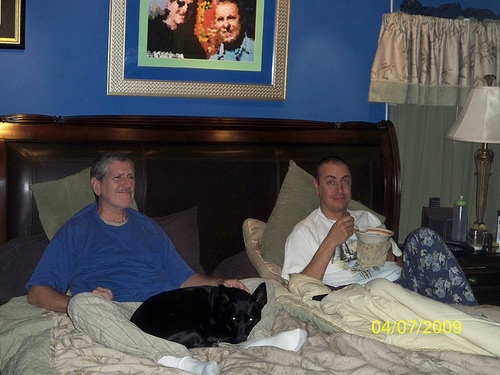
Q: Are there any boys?
A: No, there are no boys.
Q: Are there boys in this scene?
A: No, there are no boys.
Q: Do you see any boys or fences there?
A: No, there are no boys or fences.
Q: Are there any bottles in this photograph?
A: Yes, there is a bottle.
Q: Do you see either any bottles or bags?
A: Yes, there is a bottle.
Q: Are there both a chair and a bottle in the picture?
A: No, there is a bottle but no chairs.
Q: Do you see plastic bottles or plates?
A: Yes, there is a plastic bottle.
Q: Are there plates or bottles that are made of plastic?
A: Yes, the bottle is made of plastic.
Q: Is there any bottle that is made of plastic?
A: Yes, there is a bottle that is made of plastic.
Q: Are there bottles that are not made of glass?
A: Yes, there is a bottle that is made of plastic.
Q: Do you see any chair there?
A: No, there are no chairs.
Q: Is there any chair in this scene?
A: No, there are no chairs.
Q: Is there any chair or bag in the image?
A: No, there are no chairs or bags.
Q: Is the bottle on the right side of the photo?
A: Yes, the bottle is on the right of the image.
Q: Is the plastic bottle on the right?
A: Yes, the bottle is on the right of the image.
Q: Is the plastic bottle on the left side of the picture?
A: No, the bottle is on the right of the image.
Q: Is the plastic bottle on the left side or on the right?
A: The bottle is on the right of the image.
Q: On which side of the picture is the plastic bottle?
A: The bottle is on the right of the image.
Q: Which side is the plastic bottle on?
A: The bottle is on the right of the image.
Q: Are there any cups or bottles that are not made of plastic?
A: No, there is a bottle but it is made of plastic.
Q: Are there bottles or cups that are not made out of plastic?
A: No, there is a bottle but it is made of plastic.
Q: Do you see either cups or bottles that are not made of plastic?
A: No, there is a bottle but it is made of plastic.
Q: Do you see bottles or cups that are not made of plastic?
A: No, there is a bottle but it is made of plastic.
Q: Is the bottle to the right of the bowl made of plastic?
A: Yes, the bottle is made of plastic.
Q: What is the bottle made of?
A: The bottle is made of plastic.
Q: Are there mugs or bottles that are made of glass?
A: No, there is a bottle but it is made of plastic.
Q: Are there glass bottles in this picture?
A: No, there is a bottle but it is made of plastic.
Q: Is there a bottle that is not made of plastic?
A: No, there is a bottle but it is made of plastic.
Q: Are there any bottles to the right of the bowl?
A: Yes, there is a bottle to the right of the bowl.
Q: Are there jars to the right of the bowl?
A: No, there is a bottle to the right of the bowl.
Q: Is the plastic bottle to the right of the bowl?
A: Yes, the bottle is to the right of the bowl.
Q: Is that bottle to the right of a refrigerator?
A: No, the bottle is to the right of the bowl.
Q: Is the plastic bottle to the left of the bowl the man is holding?
A: No, the bottle is to the right of the bowl.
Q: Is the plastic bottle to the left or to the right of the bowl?
A: The bottle is to the right of the bowl.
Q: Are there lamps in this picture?
A: Yes, there is a lamp.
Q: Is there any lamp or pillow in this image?
A: Yes, there is a lamp.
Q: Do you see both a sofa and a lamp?
A: No, there is a lamp but no sofas.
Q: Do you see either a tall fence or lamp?
A: Yes, there is a tall lamp.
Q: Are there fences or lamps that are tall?
A: Yes, the lamp is tall.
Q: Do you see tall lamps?
A: Yes, there is a tall lamp.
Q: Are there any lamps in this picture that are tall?
A: Yes, there is a lamp that is tall.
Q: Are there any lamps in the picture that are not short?
A: Yes, there is a tall lamp.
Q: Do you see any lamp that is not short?
A: Yes, there is a tall lamp.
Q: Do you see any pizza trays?
A: No, there are no pizza trays.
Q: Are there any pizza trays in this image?
A: No, there are no pizza trays.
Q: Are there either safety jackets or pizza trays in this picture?
A: No, there are no pizza trays or safety jackets.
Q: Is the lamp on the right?
A: Yes, the lamp is on the right of the image.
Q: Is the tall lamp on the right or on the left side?
A: The lamp is on the right of the image.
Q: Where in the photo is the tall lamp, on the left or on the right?
A: The lamp is on the right of the image.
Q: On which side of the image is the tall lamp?
A: The lamp is on the right of the image.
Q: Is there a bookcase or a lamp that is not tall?
A: No, there is a lamp but it is tall.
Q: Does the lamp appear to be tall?
A: Yes, the lamp is tall.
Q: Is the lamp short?
A: No, the lamp is tall.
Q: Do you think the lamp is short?
A: No, the lamp is tall.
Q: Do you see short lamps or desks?
A: No, there is a lamp but it is tall.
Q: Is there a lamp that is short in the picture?
A: No, there is a lamp but it is tall.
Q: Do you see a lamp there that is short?
A: No, there is a lamp but it is tall.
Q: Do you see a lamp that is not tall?
A: No, there is a lamp but it is tall.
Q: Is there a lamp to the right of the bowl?
A: Yes, there is a lamp to the right of the bowl.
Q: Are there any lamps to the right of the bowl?
A: Yes, there is a lamp to the right of the bowl.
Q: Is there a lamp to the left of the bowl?
A: No, the lamp is to the right of the bowl.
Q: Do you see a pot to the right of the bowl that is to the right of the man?
A: No, there is a lamp to the right of the bowl.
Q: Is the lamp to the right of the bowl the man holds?
A: Yes, the lamp is to the right of the bowl.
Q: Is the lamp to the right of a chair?
A: No, the lamp is to the right of the bowl.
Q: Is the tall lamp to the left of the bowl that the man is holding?
A: No, the lamp is to the right of the bowl.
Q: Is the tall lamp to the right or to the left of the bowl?
A: The lamp is to the right of the bowl.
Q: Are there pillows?
A: Yes, there is a pillow.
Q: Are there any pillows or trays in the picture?
A: Yes, there is a pillow.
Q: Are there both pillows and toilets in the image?
A: No, there is a pillow but no toilets.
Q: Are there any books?
A: No, there are no books.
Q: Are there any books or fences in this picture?
A: No, there are no books or fences.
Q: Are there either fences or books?
A: No, there are no books or fences.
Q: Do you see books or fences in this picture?
A: No, there are no books or fences.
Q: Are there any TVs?
A: No, there are no tvs.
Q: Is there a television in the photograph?
A: No, there are no televisions.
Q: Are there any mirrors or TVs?
A: No, there are no TVs or mirrors.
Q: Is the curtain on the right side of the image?
A: Yes, the curtain is on the right of the image.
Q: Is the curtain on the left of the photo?
A: No, the curtain is on the right of the image.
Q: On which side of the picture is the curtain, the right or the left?
A: The curtain is on the right of the image.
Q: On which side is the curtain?
A: The curtain is on the right of the image.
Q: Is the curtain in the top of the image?
A: Yes, the curtain is in the top of the image.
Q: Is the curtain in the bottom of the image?
A: No, the curtain is in the top of the image.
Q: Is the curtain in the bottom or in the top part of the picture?
A: The curtain is in the top of the image.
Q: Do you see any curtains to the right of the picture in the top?
A: Yes, there is a curtain to the right of the picture.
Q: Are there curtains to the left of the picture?
A: No, the curtain is to the right of the picture.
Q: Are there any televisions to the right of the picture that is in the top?
A: No, there is a curtain to the right of the picture.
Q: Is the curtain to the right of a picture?
A: Yes, the curtain is to the right of a picture.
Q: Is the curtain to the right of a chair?
A: No, the curtain is to the right of a picture.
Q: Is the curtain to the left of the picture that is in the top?
A: No, the curtain is to the right of the picture.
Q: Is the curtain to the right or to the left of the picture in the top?
A: The curtain is to the right of the picture.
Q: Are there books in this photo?
A: No, there are no books.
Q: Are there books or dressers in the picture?
A: No, there are no books or dressers.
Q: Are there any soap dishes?
A: No, there are no soap dishes.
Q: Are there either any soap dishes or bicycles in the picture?
A: No, there are no soap dishes or bicycles.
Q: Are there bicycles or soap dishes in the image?
A: No, there are no soap dishes or bicycles.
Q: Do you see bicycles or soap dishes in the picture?
A: No, there are no soap dishes or bicycles.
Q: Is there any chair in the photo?
A: No, there are no chairs.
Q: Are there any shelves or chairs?
A: No, there are no chairs or shelves.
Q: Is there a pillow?
A: Yes, there is a pillow.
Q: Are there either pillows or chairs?
A: Yes, there is a pillow.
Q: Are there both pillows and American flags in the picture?
A: No, there is a pillow but no American flags.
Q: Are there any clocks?
A: No, there are no clocks.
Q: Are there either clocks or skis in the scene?
A: No, there are no clocks or skis.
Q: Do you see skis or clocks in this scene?
A: No, there are no clocks or skis.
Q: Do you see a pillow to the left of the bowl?
A: Yes, there is a pillow to the left of the bowl.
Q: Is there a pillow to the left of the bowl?
A: Yes, there is a pillow to the left of the bowl.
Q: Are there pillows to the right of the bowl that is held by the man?
A: No, the pillow is to the left of the bowl.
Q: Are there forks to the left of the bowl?
A: No, there is a pillow to the left of the bowl.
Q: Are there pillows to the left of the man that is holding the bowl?
A: Yes, there is a pillow to the left of the man.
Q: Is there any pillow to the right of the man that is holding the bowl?
A: No, the pillow is to the left of the man.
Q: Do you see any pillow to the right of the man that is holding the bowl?
A: No, the pillow is to the left of the man.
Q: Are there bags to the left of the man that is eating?
A: No, there is a pillow to the left of the man.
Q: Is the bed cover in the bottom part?
A: Yes, the bed cover is in the bottom of the image.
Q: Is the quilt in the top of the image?
A: No, the quilt is in the bottom of the image.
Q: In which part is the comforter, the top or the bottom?
A: The comforter is in the bottom of the image.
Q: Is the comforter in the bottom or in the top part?
A: The comforter is in the bottom of the image.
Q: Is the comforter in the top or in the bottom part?
A: The comforter is in the bottom of the image.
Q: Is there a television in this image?
A: No, there are no televisions.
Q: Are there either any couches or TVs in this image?
A: No, there are no TVs or couches.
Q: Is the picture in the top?
A: Yes, the picture is in the top of the image.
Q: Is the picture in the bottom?
A: No, the picture is in the top of the image.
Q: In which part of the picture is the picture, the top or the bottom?
A: The picture is in the top of the image.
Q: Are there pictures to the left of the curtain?
A: Yes, there is a picture to the left of the curtain.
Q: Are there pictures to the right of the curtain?
A: No, the picture is to the left of the curtain.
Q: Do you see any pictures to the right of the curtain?
A: No, the picture is to the left of the curtain.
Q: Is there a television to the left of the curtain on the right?
A: No, there is a picture to the left of the curtain.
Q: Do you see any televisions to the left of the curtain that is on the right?
A: No, there is a picture to the left of the curtain.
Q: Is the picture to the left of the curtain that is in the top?
A: Yes, the picture is to the left of the curtain.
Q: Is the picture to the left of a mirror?
A: No, the picture is to the left of the curtain.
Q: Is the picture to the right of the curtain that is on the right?
A: No, the picture is to the left of the curtain.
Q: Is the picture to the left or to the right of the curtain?
A: The picture is to the left of the curtain.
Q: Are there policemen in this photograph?
A: No, there are no policemen.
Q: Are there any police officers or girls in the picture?
A: No, there are no police officers or girls.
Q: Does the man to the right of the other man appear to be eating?
A: Yes, the man is eating.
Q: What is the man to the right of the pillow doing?
A: The man is eating.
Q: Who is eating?
A: The man is eating.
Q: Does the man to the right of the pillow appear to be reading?
A: No, the man is eating.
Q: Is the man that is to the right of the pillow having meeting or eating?
A: The man is eating.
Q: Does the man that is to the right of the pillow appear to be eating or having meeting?
A: The man is eating.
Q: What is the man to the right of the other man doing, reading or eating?
A: The man is eating.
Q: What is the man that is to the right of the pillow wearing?
A: The man is wearing a shirt.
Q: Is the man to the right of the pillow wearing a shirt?
A: Yes, the man is wearing a shirt.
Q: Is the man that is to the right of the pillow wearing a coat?
A: No, the man is wearing a shirt.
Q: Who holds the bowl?
A: The man holds the bowl.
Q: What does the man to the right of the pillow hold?
A: The man holds the bowl.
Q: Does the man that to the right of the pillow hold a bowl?
A: Yes, the man holds a bowl.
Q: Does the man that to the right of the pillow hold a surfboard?
A: No, the man holds a bowl.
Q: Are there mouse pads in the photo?
A: No, there are no mouse pads.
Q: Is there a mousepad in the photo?
A: No, there are no mouse pads.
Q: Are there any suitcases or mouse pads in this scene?
A: No, there are no mouse pads or suitcases.